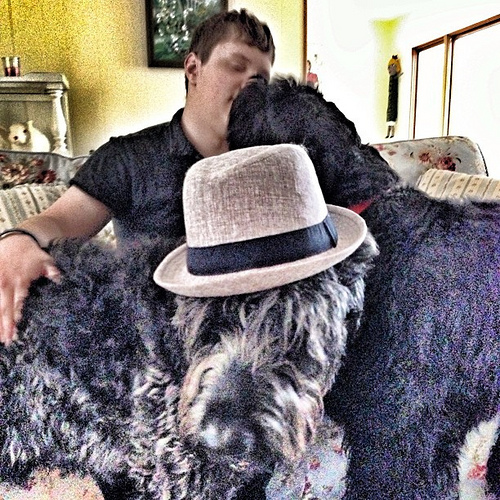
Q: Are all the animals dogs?
A: No, there are both bunnies and dogs.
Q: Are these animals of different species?
A: Yes, they are bunnies and dogs.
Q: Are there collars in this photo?
A: Yes, there is a collar.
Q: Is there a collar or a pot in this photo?
A: Yes, there is a collar.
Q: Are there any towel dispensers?
A: No, there are no towel dispensers.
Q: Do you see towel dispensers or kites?
A: No, there are no towel dispensers or kites.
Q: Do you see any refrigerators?
A: No, there are no refrigerators.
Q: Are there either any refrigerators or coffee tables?
A: No, there are no refrigerators or coffee tables.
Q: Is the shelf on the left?
A: Yes, the shelf is on the left of the image.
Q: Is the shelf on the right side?
A: No, the shelf is on the left of the image.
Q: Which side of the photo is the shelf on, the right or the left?
A: The shelf is on the left of the image.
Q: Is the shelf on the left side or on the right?
A: The shelf is on the left of the image.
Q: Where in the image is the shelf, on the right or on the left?
A: The shelf is on the left of the image.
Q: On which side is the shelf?
A: The shelf is on the left of the image.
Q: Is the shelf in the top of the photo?
A: Yes, the shelf is in the top of the image.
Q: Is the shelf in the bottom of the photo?
A: No, the shelf is in the top of the image.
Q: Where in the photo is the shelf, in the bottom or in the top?
A: The shelf is in the top of the image.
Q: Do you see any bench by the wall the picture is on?
A: No, there is a shelf by the wall.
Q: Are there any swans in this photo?
A: No, there are no swans.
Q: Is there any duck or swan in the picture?
A: No, there are no swans or ducks.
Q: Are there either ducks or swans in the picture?
A: No, there are no swans or ducks.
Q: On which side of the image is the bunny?
A: The bunny is on the left of the image.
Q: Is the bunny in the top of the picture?
A: Yes, the bunny is in the top of the image.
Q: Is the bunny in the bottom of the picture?
A: No, the bunny is in the top of the image.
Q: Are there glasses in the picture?
A: No, there are no glasses.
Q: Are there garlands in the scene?
A: No, there are no garlands.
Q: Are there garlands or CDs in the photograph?
A: No, there are no garlands or cds.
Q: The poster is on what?
A: The poster is on the wall.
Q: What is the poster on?
A: The poster is on the wall.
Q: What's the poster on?
A: The poster is on the wall.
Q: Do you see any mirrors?
A: No, there are no mirrors.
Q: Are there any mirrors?
A: No, there are no mirrors.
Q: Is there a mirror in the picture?
A: No, there are no mirrors.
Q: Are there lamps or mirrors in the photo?
A: No, there are no mirrors or lamps.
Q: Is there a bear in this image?
A: No, there are no bears.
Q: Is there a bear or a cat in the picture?
A: No, there are no bears or cats.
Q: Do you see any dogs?
A: Yes, there is a dog.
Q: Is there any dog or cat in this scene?
A: Yes, there is a dog.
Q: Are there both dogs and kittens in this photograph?
A: No, there is a dog but no kittens.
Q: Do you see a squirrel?
A: No, there are no squirrels.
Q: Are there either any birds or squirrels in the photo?
A: No, there are no squirrels or birds.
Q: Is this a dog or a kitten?
A: This is a dog.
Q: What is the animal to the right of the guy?
A: The animal is a dog.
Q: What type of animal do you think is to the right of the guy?
A: The animal is a dog.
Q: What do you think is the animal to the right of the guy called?
A: The animal is a dog.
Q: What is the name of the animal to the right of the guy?
A: The animal is a dog.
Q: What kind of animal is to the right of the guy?
A: The animal is a dog.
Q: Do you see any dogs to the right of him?
A: Yes, there is a dog to the right of the guy.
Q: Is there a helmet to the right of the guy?
A: No, there is a dog to the right of the guy.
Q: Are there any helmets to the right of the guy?
A: No, there is a dog to the right of the guy.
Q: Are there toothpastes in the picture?
A: No, there are no toothpastes.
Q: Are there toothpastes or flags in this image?
A: No, there are no toothpastes or flags.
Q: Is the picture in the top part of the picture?
A: Yes, the picture is in the top of the image.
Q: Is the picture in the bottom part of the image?
A: No, the picture is in the top of the image.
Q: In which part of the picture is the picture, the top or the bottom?
A: The picture is in the top of the image.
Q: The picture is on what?
A: The picture is on the wall.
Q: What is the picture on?
A: The picture is on the wall.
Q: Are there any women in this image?
A: No, there are no women.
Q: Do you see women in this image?
A: No, there are no women.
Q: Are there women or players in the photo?
A: No, there are no women or players.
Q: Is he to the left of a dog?
A: Yes, the guy is to the left of a dog.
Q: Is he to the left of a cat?
A: No, the guy is to the left of a dog.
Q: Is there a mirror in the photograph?
A: No, there are no mirrors.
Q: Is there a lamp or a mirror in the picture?
A: No, there are no mirrors or lamps.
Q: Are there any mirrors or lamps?
A: No, there are no mirrors or lamps.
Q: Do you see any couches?
A: Yes, there is a couch.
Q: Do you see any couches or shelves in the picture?
A: Yes, there is a couch.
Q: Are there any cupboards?
A: No, there are no cupboards.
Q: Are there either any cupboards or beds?
A: No, there are no cupboards or beds.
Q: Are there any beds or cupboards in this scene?
A: No, there are no cupboards or beds.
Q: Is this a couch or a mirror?
A: This is a couch.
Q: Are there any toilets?
A: No, there are no toilets.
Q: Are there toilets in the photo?
A: No, there are no toilets.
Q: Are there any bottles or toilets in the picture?
A: No, there are no toilets or bottles.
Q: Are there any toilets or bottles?
A: No, there are no toilets or bottles.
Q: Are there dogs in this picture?
A: Yes, there is a dog.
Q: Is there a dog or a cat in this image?
A: Yes, there is a dog.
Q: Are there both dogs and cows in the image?
A: No, there is a dog but no cows.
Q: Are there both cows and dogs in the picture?
A: No, there is a dog but no cows.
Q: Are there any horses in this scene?
A: No, there are no horses.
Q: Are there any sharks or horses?
A: No, there are no horses or sharks.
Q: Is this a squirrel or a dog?
A: This is a dog.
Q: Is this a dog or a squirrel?
A: This is a dog.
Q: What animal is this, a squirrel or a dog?
A: This is a dog.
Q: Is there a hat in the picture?
A: Yes, there is a hat.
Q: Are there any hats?
A: Yes, there is a hat.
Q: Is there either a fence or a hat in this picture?
A: Yes, there is a hat.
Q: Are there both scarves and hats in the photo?
A: No, there is a hat but no scarves.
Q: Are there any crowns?
A: No, there are no crowns.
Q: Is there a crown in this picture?
A: No, there are no crowns.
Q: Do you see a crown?
A: No, there are no crowns.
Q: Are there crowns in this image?
A: No, there are no crowns.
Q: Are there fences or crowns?
A: No, there are no crowns or fences.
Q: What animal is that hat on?
A: The hat is on the dog.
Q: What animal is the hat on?
A: The hat is on the dog.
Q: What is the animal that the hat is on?
A: The animal is a dog.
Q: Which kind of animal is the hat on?
A: The hat is on the dog.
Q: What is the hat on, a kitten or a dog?
A: The hat is on a dog.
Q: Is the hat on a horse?
A: No, the hat is on the dog.